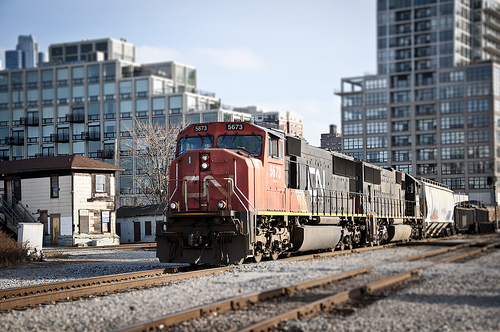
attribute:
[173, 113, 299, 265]
train — coming, moving, below, white, black, red, large, long, here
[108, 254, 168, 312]
tracks — brown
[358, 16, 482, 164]
building — tall, large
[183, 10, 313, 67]
sky — above, bright, blue, high